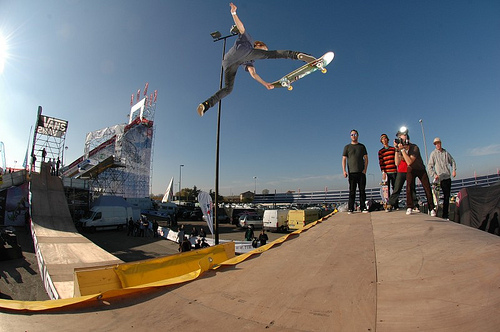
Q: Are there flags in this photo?
A: Yes, there is a flag.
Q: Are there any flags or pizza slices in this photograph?
A: Yes, there is a flag.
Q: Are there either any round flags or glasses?
A: Yes, there is a round flag.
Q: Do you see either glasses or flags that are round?
A: Yes, the flag is round.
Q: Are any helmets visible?
A: No, there are no helmets.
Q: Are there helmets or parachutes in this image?
A: No, there are no helmets or parachutes.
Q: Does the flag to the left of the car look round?
A: Yes, the flag is round.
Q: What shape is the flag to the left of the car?
A: The flag is round.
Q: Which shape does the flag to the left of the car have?
A: The flag has round shape.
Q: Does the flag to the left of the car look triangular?
A: No, the flag is round.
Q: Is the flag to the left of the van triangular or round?
A: The flag is round.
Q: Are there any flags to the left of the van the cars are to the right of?
A: Yes, there is a flag to the left of the van.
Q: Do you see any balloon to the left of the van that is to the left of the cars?
A: No, there is a flag to the left of the van.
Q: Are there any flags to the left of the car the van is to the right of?
A: Yes, there is a flag to the left of the car.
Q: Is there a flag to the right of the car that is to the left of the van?
A: No, the flag is to the left of the car.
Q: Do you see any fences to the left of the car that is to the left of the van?
A: No, there is a flag to the left of the car.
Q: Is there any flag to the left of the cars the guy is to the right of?
A: Yes, there is a flag to the left of the cars.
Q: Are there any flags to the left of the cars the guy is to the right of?
A: Yes, there is a flag to the left of the cars.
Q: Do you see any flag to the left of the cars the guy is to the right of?
A: Yes, there is a flag to the left of the cars.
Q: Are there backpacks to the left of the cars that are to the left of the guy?
A: No, there is a flag to the left of the cars.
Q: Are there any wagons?
A: No, there are no wagons.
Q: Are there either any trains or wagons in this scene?
A: No, there are no wagons or trains.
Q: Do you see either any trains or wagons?
A: No, there are no wagons or trains.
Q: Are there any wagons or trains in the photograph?
A: No, there are no wagons or trains.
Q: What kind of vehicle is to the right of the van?
A: The vehicles are cars.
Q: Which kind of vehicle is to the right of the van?
A: The vehicles are cars.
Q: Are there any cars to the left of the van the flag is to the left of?
A: No, the cars are to the right of the van.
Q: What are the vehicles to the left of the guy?
A: The vehicles are cars.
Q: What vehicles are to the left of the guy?
A: The vehicles are cars.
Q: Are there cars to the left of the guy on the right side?
A: Yes, there are cars to the left of the guy.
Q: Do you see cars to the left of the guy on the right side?
A: Yes, there are cars to the left of the guy.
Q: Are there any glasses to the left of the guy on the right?
A: No, there are cars to the left of the guy.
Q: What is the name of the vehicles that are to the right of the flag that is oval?
A: The vehicles are cars.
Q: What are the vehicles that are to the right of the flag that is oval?
A: The vehicles are cars.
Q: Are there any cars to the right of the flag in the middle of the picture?
A: Yes, there are cars to the right of the flag.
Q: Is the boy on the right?
A: Yes, the boy is on the right of the image.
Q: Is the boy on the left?
A: No, the boy is on the right of the image.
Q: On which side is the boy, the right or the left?
A: The boy is on the right of the image.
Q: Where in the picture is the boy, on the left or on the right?
A: The boy is on the right of the image.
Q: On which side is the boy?
A: The boy is on the right of the image.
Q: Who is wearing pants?
A: The boy is wearing pants.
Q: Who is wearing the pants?
A: The boy is wearing pants.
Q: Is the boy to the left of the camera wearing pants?
A: Yes, the boy is wearing pants.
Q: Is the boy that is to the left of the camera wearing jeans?
A: No, the boy is wearing pants.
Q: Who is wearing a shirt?
A: The boy is wearing a shirt.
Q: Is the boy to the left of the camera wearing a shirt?
A: Yes, the boy is wearing a shirt.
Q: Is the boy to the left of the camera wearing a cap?
A: No, the boy is wearing a shirt.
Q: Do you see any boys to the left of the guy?
A: Yes, there is a boy to the left of the guy.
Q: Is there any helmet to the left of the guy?
A: No, there is a boy to the left of the guy.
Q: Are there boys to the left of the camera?
A: Yes, there is a boy to the left of the camera.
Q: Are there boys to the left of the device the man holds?
A: Yes, there is a boy to the left of the camera.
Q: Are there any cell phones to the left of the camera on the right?
A: No, there is a boy to the left of the camera.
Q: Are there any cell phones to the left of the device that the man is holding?
A: No, there is a boy to the left of the camera.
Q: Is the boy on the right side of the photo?
A: Yes, the boy is on the right of the image.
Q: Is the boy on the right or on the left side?
A: The boy is on the right of the image.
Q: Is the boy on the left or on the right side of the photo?
A: The boy is on the right of the image.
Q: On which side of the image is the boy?
A: The boy is on the right of the image.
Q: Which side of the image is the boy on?
A: The boy is on the right of the image.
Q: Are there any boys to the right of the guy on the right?
A: No, the boy is to the left of the guy.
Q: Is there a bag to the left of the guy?
A: No, there is a boy to the left of the guy.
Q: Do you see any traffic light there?
A: No, there are no traffic lights.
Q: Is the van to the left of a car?
A: No, the van is to the right of a car.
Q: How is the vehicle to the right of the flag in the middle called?
A: The vehicle is a van.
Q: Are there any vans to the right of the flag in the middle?
A: Yes, there is a van to the right of the flag.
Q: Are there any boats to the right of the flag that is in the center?
A: No, there is a van to the right of the flag.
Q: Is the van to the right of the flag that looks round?
A: Yes, the van is to the right of the flag.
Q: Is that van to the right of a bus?
A: No, the van is to the right of the flag.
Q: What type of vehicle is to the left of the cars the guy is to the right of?
A: The vehicle is a van.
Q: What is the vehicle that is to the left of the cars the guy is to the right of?
A: The vehicle is a van.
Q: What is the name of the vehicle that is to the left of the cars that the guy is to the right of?
A: The vehicle is a van.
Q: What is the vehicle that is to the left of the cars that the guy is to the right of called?
A: The vehicle is a van.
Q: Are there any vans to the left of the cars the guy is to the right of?
A: Yes, there is a van to the left of the cars.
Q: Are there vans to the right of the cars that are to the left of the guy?
A: No, the van is to the left of the cars.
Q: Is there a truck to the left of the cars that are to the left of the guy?
A: No, there is a van to the left of the cars.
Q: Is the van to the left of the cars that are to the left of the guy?
A: Yes, the van is to the left of the cars.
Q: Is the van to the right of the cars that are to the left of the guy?
A: No, the van is to the left of the cars.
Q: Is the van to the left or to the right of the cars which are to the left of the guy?
A: The van is to the left of the cars.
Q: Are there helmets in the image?
A: No, there are no helmets.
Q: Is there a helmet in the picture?
A: No, there are no helmets.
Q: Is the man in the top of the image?
A: Yes, the man is in the top of the image.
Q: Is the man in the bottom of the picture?
A: No, the man is in the top of the image.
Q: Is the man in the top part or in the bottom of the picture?
A: The man is in the top of the image.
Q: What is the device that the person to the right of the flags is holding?
A: The device is a camera.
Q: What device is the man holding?
A: The man is holding the camera.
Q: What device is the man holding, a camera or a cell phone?
A: The man is holding a camera.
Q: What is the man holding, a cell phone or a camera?
A: The man is holding a camera.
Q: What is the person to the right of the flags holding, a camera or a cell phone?
A: The man is holding a camera.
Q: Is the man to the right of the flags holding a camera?
A: Yes, the man is holding a camera.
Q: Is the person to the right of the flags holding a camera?
A: Yes, the man is holding a camera.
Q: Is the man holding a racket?
A: No, the man is holding a camera.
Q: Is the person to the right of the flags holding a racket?
A: No, the man is holding a camera.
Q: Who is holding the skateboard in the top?
A: The man is holding the skateboard.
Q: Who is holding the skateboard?
A: The man is holding the skateboard.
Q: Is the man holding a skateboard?
A: Yes, the man is holding a skateboard.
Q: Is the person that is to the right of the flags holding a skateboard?
A: Yes, the man is holding a skateboard.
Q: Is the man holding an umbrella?
A: No, the man is holding a skateboard.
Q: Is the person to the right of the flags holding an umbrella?
A: No, the man is holding a skateboard.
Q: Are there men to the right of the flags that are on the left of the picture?
A: Yes, there is a man to the right of the flags.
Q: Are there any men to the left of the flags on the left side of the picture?
A: No, the man is to the right of the flags.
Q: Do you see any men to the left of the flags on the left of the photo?
A: No, the man is to the right of the flags.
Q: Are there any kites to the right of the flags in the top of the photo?
A: No, there is a man to the right of the flags.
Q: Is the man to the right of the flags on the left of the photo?
A: Yes, the man is to the right of the flags.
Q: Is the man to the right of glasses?
A: No, the man is to the right of the flags.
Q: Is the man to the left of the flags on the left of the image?
A: No, the man is to the right of the flags.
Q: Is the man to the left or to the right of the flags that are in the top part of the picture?
A: The man is to the right of the flags.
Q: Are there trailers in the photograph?
A: No, there are no trailers.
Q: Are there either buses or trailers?
A: No, there are no trailers or buses.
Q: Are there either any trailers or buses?
A: No, there are no trailers or buses.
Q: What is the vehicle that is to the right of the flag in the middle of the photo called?
A: The vehicle is a car.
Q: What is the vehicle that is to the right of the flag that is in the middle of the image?
A: The vehicle is a car.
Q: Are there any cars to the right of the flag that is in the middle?
A: Yes, there is a car to the right of the flag.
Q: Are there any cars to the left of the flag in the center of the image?
A: No, the car is to the right of the flag.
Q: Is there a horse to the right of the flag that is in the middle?
A: No, there is a car to the right of the flag.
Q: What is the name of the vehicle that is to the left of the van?
A: The vehicle is a car.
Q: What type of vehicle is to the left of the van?
A: The vehicle is a car.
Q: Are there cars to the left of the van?
A: Yes, there is a car to the left of the van.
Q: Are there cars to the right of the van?
A: No, the car is to the left of the van.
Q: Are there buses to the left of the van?
A: No, there is a car to the left of the van.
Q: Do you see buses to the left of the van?
A: No, there is a car to the left of the van.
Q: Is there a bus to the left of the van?
A: No, there is a car to the left of the van.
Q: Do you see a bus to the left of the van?
A: No, there is a car to the left of the van.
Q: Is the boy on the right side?
A: Yes, the boy is on the right of the image.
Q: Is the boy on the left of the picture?
A: No, the boy is on the right of the image.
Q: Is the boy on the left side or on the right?
A: The boy is on the right of the image.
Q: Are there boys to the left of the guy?
A: Yes, there is a boy to the left of the guy.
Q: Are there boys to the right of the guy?
A: No, the boy is to the left of the guy.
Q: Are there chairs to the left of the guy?
A: No, there is a boy to the left of the guy.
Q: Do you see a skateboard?
A: Yes, there is a skateboard.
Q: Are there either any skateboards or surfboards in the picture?
A: Yes, there is a skateboard.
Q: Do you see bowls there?
A: No, there are no bowls.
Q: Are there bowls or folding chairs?
A: No, there are no bowls or folding chairs.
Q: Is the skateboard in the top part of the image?
A: Yes, the skateboard is in the top of the image.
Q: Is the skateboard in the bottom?
A: No, the skateboard is in the top of the image.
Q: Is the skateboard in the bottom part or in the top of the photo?
A: The skateboard is in the top of the image.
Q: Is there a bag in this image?
A: No, there are no bags.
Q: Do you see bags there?
A: No, there are no bags.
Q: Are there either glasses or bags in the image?
A: No, there are no bags or glasses.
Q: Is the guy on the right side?
A: Yes, the guy is on the right of the image.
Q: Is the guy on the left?
A: No, the guy is on the right of the image.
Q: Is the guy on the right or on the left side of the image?
A: The guy is on the right of the image.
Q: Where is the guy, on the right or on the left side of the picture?
A: The guy is on the right of the image.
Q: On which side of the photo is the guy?
A: The guy is on the right of the image.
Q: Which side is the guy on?
A: The guy is on the right of the image.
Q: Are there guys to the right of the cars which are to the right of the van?
A: Yes, there is a guy to the right of the cars.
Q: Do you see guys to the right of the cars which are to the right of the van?
A: Yes, there is a guy to the right of the cars.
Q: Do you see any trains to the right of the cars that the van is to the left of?
A: No, there is a guy to the right of the cars.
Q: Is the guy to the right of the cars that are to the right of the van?
A: Yes, the guy is to the right of the cars.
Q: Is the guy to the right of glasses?
A: No, the guy is to the right of the cars.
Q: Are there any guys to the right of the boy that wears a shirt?
A: Yes, there is a guy to the right of the boy.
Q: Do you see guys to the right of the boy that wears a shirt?
A: Yes, there is a guy to the right of the boy.